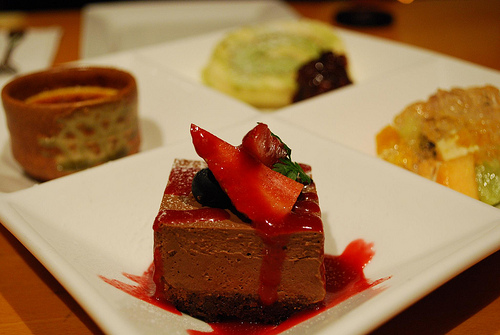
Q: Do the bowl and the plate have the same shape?
A: No, the bowl is round and the plate is square.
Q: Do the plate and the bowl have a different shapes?
A: Yes, the plate is round and the bowl is square.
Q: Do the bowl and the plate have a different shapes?
A: Yes, the bowl is round and the plate is square.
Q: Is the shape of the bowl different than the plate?
A: Yes, the bowl is round and the plate is square.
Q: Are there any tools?
A: No, there are no tools.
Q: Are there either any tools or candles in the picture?
A: No, there are no tools or candles.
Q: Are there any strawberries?
A: Yes, there is a strawberry.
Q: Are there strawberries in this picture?
A: Yes, there is a strawberry.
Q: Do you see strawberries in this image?
A: Yes, there is a strawberry.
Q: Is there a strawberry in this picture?
A: Yes, there is a strawberry.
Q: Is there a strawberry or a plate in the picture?
A: Yes, there is a strawberry.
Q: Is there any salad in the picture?
A: No, there is no salad.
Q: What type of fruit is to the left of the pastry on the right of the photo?
A: The fruit is a strawberry.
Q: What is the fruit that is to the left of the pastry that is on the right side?
A: The fruit is a strawberry.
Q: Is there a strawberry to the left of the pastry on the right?
A: Yes, there is a strawberry to the left of the pastry.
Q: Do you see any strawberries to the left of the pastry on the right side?
A: Yes, there is a strawberry to the left of the pastry.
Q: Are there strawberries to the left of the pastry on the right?
A: Yes, there is a strawberry to the left of the pastry.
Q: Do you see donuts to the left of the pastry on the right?
A: No, there is a strawberry to the left of the pastry.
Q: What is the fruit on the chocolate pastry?
A: The fruit is a strawberry.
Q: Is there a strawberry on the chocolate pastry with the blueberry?
A: Yes, there is a strawberry on the pastry.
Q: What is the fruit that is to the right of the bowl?
A: The fruit is a strawberry.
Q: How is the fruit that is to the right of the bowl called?
A: The fruit is a strawberry.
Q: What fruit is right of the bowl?
A: The fruit is a strawberry.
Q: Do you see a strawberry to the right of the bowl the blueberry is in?
A: Yes, there is a strawberry to the right of the bowl.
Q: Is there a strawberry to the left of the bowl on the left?
A: No, the strawberry is to the right of the bowl.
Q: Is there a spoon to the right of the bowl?
A: No, there is a strawberry to the right of the bowl.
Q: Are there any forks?
A: Yes, there is a fork.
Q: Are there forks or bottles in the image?
A: Yes, there is a fork.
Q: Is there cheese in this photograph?
A: No, there is no cheese.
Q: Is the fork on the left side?
A: Yes, the fork is on the left of the image.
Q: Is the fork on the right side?
A: No, the fork is on the left of the image.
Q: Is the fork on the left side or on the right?
A: The fork is on the left of the image.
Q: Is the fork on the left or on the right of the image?
A: The fork is on the left of the image.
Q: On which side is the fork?
A: The fork is on the left of the image.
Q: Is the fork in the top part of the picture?
A: Yes, the fork is in the top of the image.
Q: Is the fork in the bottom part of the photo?
A: No, the fork is in the top of the image.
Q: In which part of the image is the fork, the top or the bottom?
A: The fork is in the top of the image.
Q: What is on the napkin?
A: The fork is on the napkin.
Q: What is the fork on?
A: The fork is on the napkin.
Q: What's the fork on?
A: The fork is on the napkin.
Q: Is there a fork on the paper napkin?
A: Yes, there is a fork on the napkin.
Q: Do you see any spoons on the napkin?
A: No, there is a fork on the napkin.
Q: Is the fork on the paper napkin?
A: Yes, the fork is on the napkin.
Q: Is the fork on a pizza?
A: No, the fork is on the napkin.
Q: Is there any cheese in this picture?
A: No, there is no cheese.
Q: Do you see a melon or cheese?
A: No, there are no cheese or melons.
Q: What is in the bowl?
A: The blueberry is in the bowl.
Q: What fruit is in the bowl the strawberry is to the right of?
A: The fruit is a blueberry.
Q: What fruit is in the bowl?
A: The fruit is a blueberry.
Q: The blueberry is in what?
A: The blueberry is in the bowl.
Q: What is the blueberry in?
A: The blueberry is in the bowl.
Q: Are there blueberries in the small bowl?
A: Yes, there is a blueberry in the bowl.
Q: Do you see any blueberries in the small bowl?
A: Yes, there is a blueberry in the bowl.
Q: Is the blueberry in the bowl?
A: Yes, the blueberry is in the bowl.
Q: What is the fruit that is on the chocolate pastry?
A: The fruit is a blueberry.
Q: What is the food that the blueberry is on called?
A: The food is a pastry.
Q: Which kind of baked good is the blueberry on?
A: The blueberry is on the pastry.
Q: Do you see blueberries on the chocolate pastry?
A: Yes, there is a blueberry on the pastry.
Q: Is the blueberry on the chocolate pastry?
A: Yes, the blueberry is on the pastry.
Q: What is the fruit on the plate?
A: The fruit is a blueberry.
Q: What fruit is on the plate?
A: The fruit is a blueberry.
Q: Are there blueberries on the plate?
A: Yes, there is a blueberry on the plate.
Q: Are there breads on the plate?
A: No, there is a blueberry on the plate.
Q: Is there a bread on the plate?
A: No, there is a blueberry on the plate.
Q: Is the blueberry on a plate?
A: Yes, the blueberry is on a plate.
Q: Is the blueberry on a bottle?
A: No, the blueberry is on a plate.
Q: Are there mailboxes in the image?
A: No, there are no mailboxes.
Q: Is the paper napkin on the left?
A: Yes, the napkin is on the left of the image.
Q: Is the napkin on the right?
A: No, the napkin is on the left of the image.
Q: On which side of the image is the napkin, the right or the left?
A: The napkin is on the left of the image.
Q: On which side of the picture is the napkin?
A: The napkin is on the left of the image.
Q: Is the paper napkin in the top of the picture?
A: Yes, the napkin is in the top of the image.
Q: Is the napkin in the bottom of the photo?
A: No, the napkin is in the top of the image.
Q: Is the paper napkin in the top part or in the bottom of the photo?
A: The napkin is in the top of the image.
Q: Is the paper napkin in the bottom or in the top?
A: The napkin is in the top of the image.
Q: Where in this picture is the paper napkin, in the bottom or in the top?
A: The napkin is in the top of the image.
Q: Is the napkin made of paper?
A: Yes, the napkin is made of paper.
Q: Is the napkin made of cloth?
A: No, the napkin is made of paper.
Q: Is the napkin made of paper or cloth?
A: The napkin is made of paper.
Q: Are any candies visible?
A: No, there are no candies.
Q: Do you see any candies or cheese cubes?
A: No, there are no candies or cheese cubes.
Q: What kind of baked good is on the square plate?
A: The food is a pastry.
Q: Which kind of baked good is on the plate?
A: The food is a pastry.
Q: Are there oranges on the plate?
A: No, there is a pastry on the plate.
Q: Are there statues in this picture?
A: No, there are no statues.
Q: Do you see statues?
A: No, there are no statues.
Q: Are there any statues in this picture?
A: No, there are no statues.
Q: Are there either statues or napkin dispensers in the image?
A: No, there are no statues or napkin dispensers.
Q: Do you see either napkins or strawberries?
A: Yes, there is a strawberry.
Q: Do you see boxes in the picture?
A: No, there are no boxes.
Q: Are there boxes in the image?
A: No, there are no boxes.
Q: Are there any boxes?
A: No, there are no boxes.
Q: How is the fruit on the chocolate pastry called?
A: The fruit is a strawberry.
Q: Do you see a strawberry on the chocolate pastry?
A: Yes, there is a strawberry on the pastry.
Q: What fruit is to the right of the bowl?
A: The fruit is a strawberry.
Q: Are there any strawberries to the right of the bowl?
A: Yes, there is a strawberry to the right of the bowl.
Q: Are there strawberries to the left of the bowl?
A: No, the strawberry is to the right of the bowl.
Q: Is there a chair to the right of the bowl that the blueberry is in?
A: No, there is a strawberry to the right of the bowl.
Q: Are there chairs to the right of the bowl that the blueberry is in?
A: No, there is a strawberry to the right of the bowl.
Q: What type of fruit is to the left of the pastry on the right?
A: The fruit is a strawberry.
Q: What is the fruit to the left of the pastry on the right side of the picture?
A: The fruit is a strawberry.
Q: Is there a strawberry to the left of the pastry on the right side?
A: Yes, there is a strawberry to the left of the pastry.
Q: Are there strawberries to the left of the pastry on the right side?
A: Yes, there is a strawberry to the left of the pastry.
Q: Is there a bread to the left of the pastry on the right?
A: No, there is a strawberry to the left of the pastry.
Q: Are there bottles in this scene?
A: No, there are no bottles.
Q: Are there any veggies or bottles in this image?
A: No, there are no bottles or veggies.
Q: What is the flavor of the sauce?
A: That is a strawberry sauce.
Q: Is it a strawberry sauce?
A: Yes, that is a strawberry sauce.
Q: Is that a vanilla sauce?
A: No, that is a strawberry sauce.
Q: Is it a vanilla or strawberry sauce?
A: That is a strawberry sauce.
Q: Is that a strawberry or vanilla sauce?
A: That is a strawberry sauce.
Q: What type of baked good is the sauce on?
A: The sauce is on the pastry.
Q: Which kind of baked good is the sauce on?
A: The sauce is on the pastry.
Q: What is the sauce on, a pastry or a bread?
A: The sauce is on a pastry.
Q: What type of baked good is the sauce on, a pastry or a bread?
A: The sauce is on a pastry.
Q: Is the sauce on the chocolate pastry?
A: Yes, the sauce is on the pastry.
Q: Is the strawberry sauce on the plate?
A: Yes, the sauce is on the plate.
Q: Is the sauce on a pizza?
A: No, the sauce is on the plate.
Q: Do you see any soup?
A: No, there is no soup.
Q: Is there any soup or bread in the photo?
A: No, there are no soup or breads.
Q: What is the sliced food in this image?
A: The food is a pastry.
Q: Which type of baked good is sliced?
A: The baked good is a pastry.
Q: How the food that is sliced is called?
A: The food is a pastry.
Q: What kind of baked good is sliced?
A: The baked good is a pastry.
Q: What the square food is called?
A: The food is a pastry.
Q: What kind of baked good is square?
A: The baked good is a pastry.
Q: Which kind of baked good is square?
A: The baked good is a pastry.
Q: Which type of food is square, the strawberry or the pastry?
A: The pastry is square.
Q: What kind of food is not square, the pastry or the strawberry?
A: The strawberry is not square.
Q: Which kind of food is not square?
A: The food is a strawberry.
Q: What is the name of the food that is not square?
A: The food is a strawberry.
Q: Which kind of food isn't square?
A: The food is a strawberry.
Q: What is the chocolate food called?
A: The food is a pastry.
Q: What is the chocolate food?
A: The food is a pastry.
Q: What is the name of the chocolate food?
A: The food is a pastry.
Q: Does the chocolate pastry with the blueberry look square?
A: Yes, the pastry is square.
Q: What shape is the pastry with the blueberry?
A: The pastry is square.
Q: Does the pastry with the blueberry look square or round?
A: The pastry is square.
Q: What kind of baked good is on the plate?
A: The food is a pastry.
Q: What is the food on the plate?
A: The food is a pastry.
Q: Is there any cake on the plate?
A: No, there is a pastry on the plate.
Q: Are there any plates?
A: Yes, there is a plate.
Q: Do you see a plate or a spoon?
A: Yes, there is a plate.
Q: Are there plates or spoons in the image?
A: Yes, there is a plate.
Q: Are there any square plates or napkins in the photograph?
A: Yes, there is a square plate.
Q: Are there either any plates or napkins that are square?
A: Yes, the plate is square.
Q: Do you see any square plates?
A: Yes, there is a square plate.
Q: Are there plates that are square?
A: Yes, there is a plate that is square.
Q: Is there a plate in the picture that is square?
A: Yes, there is a plate that is square.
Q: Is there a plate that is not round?
A: Yes, there is a square plate.